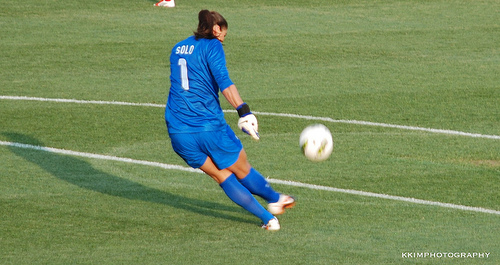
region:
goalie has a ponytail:
[193, 3, 227, 46]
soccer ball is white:
[301, 126, 335, 159]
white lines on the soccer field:
[390, 97, 476, 237]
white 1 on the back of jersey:
[170, 56, 201, 96]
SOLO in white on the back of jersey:
[165, 35, 197, 57]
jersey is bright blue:
[199, 57, 220, 110]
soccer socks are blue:
[250, 172, 264, 221]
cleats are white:
[263, 184, 288, 247]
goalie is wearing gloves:
[233, 89, 279, 153]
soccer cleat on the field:
[146, 3, 189, 16]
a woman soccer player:
[162, 7, 299, 233]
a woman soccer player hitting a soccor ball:
[159, 7, 336, 233]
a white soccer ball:
[295, 117, 336, 162]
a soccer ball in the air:
[291, 121, 346, 176]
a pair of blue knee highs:
[222, 165, 282, 226]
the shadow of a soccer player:
[2, 125, 257, 231]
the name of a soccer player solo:
[172, 43, 195, 57]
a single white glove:
[236, 104, 261, 141]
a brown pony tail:
[192, 6, 221, 38]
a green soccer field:
[1, 1, 498, 263]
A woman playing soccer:
[165, 4, 302, 235]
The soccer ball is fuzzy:
[301, 122, 337, 167]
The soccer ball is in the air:
[299, 128, 334, 165]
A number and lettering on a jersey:
[168, 35, 210, 100]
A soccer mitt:
[236, 98, 261, 140]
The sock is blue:
[243, 169, 283, 203]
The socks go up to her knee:
[225, 138, 281, 230]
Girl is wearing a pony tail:
[194, 7, 234, 47]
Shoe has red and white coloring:
[270, 190, 297, 221]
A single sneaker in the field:
[151, 0, 178, 7]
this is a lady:
[161, 4, 288, 246]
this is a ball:
[296, 114, 350, 165]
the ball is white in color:
[303, 123, 333, 159]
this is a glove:
[237, 105, 259, 133]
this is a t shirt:
[187, 83, 220, 129]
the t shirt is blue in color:
[190, 96, 214, 121]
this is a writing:
[397, 245, 496, 262]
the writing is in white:
[396, 245, 491, 263]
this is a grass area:
[361, 43, 493, 171]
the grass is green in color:
[343, 28, 458, 90]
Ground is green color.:
[39, 55, 440, 250]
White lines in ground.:
[81, 57, 380, 222]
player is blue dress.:
[137, 38, 308, 241]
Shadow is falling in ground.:
[17, 133, 256, 226]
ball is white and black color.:
[285, 110, 367, 200]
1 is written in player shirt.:
[163, 43, 205, 106]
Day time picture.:
[53, 15, 465, 217]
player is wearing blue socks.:
[224, 164, 324, 234]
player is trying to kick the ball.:
[151, 30, 350, 225]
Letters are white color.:
[170, 35, 205, 94]